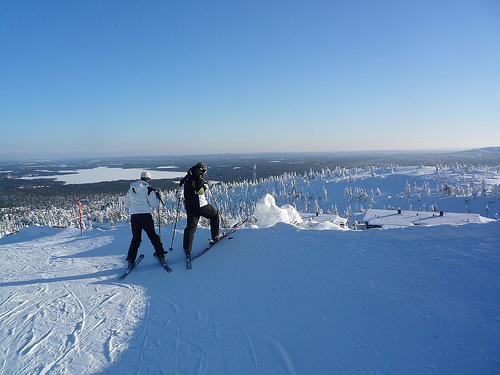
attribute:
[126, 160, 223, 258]
people — skiing, skiiing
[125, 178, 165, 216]
jacket — white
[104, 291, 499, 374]
snow — white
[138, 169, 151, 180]
hat — white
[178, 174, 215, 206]
jacket — black, white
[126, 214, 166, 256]
pants — black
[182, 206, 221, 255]
pants — black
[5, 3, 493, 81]
sky — blue, clear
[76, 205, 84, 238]
safety pole — orange